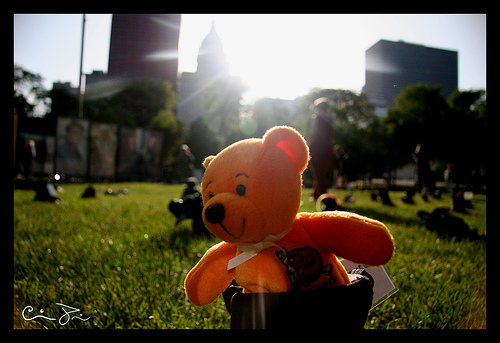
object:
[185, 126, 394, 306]
teddy bear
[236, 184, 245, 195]
eye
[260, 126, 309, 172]
ear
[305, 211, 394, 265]
arm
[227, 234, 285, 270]
bow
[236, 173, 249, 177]
eyebrow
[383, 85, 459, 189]
tree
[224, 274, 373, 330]
bucket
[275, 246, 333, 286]
beaver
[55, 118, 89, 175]
bill boards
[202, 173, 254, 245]
teddy-bear's face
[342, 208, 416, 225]
shadow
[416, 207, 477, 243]
person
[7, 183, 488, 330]
field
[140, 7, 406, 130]
rays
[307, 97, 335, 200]
person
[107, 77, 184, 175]
trees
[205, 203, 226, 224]
bear nose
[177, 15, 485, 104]
sky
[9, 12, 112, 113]
sky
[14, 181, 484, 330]
grass